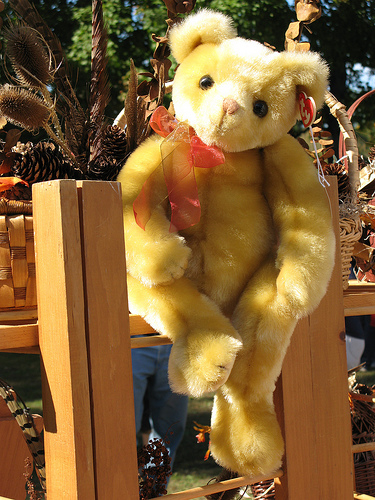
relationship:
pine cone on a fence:
[7, 139, 79, 181] [4, 223, 373, 498]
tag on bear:
[295, 86, 319, 129] [111, 10, 330, 479]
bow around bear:
[139, 140, 231, 211] [133, 43, 303, 352]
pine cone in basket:
[7, 139, 79, 181] [0, 199, 42, 349]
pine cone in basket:
[7, 139, 79, 181] [341, 97, 359, 282]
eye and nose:
[196, 73, 219, 96] [216, 90, 241, 122]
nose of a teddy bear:
[216, 90, 241, 122] [170, 39, 308, 209]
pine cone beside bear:
[87, 119, 130, 179] [111, 10, 330, 479]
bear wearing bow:
[111, 10, 330, 479] [131, 105, 227, 232]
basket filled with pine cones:
[0, 198, 36, 324] [7, 140, 67, 183]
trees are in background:
[2, 3, 374, 159] [0, 3, 372, 219]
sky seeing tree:
[351, 68, 367, 87] [123, 3, 368, 193]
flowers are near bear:
[0, 168, 28, 201] [111, 10, 330, 479]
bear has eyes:
[111, 10, 330, 479] [196, 72, 273, 117]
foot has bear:
[211, 402, 283, 483] [111, 10, 330, 479]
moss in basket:
[336, 177, 359, 220] [313, 201, 373, 307]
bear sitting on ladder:
[111, 10, 330, 479] [30, 171, 139, 494]